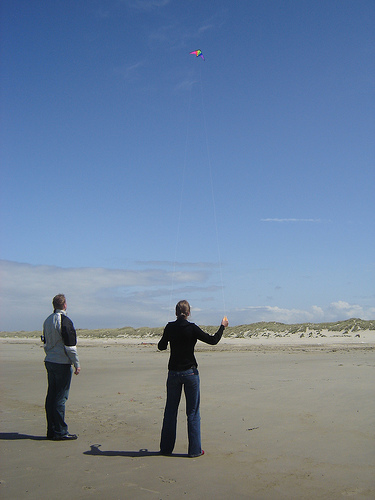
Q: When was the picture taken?
A: Daytime.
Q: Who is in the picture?
A: A man and a woman.